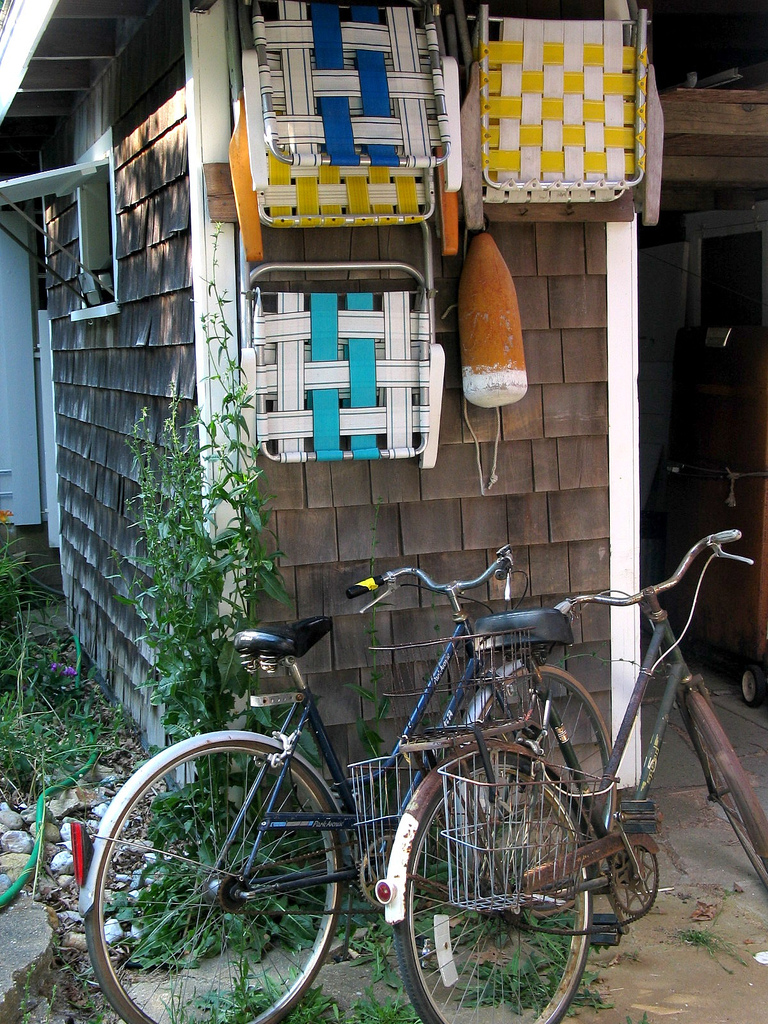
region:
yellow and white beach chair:
[475, 0, 651, 211]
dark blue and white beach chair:
[247, 0, 455, 168]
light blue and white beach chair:
[237, 210, 446, 471]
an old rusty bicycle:
[375, 527, 765, 1021]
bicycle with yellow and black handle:
[70, 539, 618, 1021]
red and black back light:
[57, 815, 97, 889]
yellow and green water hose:
[0, 582, 103, 910]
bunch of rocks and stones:
[0, 705, 198, 1019]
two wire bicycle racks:
[345, 744, 620, 915]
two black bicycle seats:
[223, 602, 577, 674]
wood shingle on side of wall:
[486, 439, 533, 502]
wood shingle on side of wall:
[418, 442, 482, 501]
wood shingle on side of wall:
[397, 497, 463, 551]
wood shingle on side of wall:
[323, 501, 403, 560]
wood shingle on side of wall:
[272, 505, 336, 567]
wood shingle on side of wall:
[326, 455, 367, 510]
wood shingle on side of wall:
[302, 461, 332, 505]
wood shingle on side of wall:
[256, 454, 304, 513]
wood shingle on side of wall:
[522, 328, 564, 386]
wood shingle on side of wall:
[514, 276, 548, 331]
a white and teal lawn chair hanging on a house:
[239, 212, 445, 476]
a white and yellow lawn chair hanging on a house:
[457, 2, 662, 236]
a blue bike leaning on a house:
[66, 551, 520, 1019]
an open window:
[0, 153, 116, 317]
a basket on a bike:
[435, 751, 578, 901]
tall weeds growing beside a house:
[100, 277, 284, 939]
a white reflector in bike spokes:
[429, 913, 457, 988]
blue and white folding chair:
[241, 249, 459, 475]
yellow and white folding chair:
[482, 3, 659, 209]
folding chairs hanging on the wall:
[231, 6, 669, 481]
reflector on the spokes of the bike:
[431, 912, 470, 987]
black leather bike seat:
[224, 607, 352, 660]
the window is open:
[0, 109, 151, 331]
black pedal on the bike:
[579, 899, 632, 958]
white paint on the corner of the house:
[610, 220, 657, 797]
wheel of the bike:
[114, 862, 316, 1022]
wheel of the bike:
[432, 871, 617, 997]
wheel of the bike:
[686, 722, 766, 875]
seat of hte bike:
[462, 638, 510, 666]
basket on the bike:
[420, 802, 568, 906]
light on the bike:
[371, 880, 397, 912]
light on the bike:
[70, 827, 88, 895]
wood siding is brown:
[547, 485, 612, 540]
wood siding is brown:
[507, 492, 551, 543]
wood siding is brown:
[459, 491, 509, 550]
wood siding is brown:
[400, 495, 464, 554]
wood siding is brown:
[337, 502, 401, 560]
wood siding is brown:
[277, 505, 340, 564]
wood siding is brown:
[333, 459, 375, 507]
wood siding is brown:
[376, 458, 418, 504]